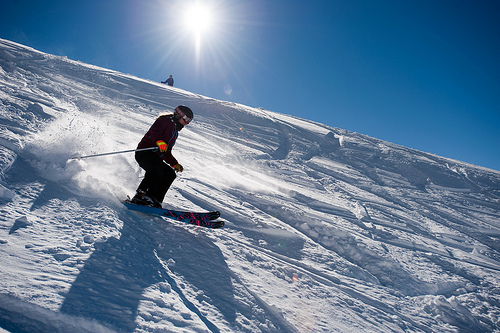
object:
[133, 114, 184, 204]
clothes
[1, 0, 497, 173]
sky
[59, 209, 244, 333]
shadow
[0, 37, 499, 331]
snow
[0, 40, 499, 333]
hill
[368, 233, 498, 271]
tracks.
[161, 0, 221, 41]
sun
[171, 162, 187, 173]
gloves.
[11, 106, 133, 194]
cloud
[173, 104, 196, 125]
helmet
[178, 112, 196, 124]
goggles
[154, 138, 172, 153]
glove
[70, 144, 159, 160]
pole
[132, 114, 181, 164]
jacket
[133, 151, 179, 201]
pants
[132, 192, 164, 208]
boots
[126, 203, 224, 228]
skis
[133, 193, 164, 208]
feet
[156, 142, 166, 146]
stripe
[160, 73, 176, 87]
skier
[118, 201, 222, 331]
tracks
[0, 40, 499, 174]
edge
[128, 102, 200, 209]
man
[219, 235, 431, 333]
prints